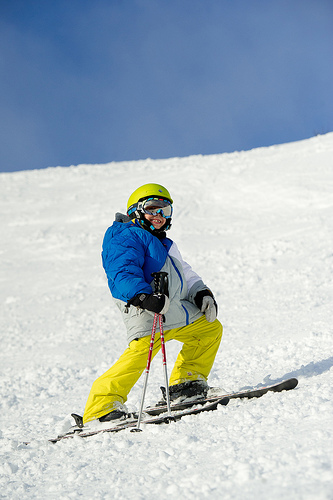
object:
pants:
[81, 340, 165, 421]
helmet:
[125, 182, 173, 208]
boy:
[82, 182, 223, 430]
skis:
[70, 397, 229, 427]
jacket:
[100, 210, 217, 343]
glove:
[199, 295, 216, 324]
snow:
[1, 179, 88, 272]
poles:
[135, 311, 158, 429]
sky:
[0, 1, 332, 128]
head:
[126, 182, 172, 232]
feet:
[82, 395, 138, 430]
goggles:
[141, 197, 171, 218]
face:
[139, 196, 172, 231]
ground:
[0, 253, 333, 499]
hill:
[0, 130, 332, 498]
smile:
[146, 214, 164, 230]